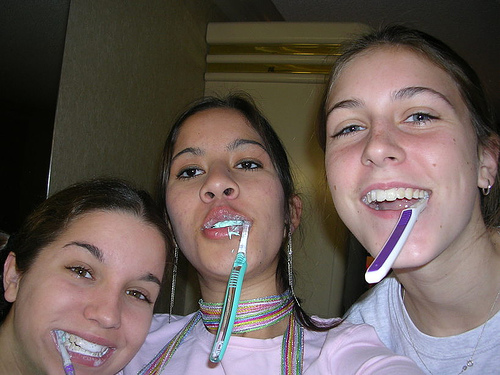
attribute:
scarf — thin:
[133, 297, 305, 372]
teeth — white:
[0, 175, 174, 373]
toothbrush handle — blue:
[355, 204, 433, 284]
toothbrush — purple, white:
[49, 330, 78, 370]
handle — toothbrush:
[318, 179, 424, 325]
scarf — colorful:
[138, 287, 306, 373]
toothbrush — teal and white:
[183, 215, 250, 370]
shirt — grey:
[346, 272, 498, 374]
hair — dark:
[132, 77, 307, 320]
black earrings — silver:
[477, 175, 497, 200]